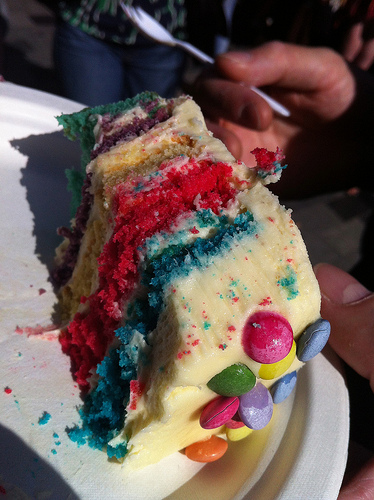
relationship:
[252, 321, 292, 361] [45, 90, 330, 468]
candy on cake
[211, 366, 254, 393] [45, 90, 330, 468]
candy on cake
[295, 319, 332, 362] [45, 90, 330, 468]
candy on cake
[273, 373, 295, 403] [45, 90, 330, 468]
candy on cake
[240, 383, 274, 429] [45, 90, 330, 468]
candy on cake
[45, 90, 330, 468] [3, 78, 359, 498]
cake on plate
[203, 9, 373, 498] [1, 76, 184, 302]
man holds plate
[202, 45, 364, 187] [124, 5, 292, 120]
hand holds spork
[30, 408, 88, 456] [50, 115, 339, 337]
crumbs on cake